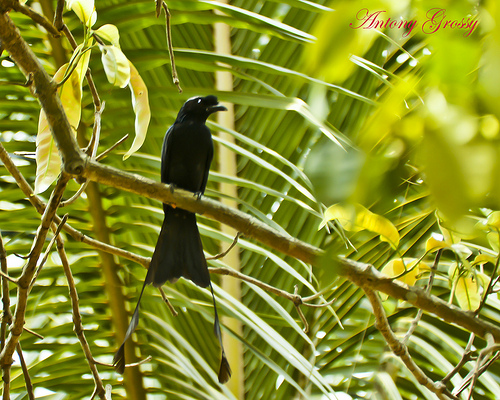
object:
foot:
[166, 182, 177, 194]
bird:
[143, 94, 228, 290]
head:
[175, 93, 227, 123]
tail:
[146, 212, 211, 289]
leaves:
[313, 201, 404, 255]